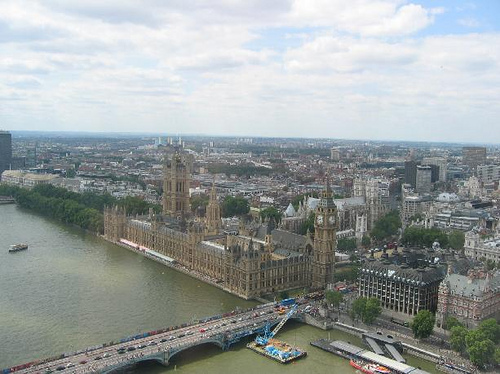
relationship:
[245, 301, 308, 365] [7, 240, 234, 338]
barge on river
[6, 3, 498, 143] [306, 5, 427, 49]
sky has clouds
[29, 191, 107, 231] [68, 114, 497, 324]
bushes in city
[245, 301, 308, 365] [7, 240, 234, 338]
barge in river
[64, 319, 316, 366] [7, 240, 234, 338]
bridge over river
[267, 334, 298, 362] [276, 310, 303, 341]
barge has crane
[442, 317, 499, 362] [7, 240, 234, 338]
trees along river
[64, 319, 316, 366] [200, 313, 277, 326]
bridge has cars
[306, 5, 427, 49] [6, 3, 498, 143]
clouds in sky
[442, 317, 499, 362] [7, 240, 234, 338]
trees near river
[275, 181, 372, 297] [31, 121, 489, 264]
building in background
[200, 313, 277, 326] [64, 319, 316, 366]
cars on bridge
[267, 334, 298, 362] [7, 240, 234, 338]
barge on river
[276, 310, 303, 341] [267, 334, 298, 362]
crane on barge